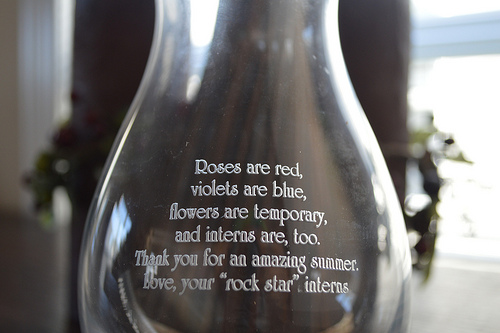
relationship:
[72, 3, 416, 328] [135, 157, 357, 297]
vase with writing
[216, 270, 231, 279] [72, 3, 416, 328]
quotation marks on vase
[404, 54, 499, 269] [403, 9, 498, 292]
window with frame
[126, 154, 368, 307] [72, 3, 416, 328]
etched poem etched into vase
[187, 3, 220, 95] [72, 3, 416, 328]
reflection seen through vase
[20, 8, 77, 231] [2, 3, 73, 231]
window with blinds